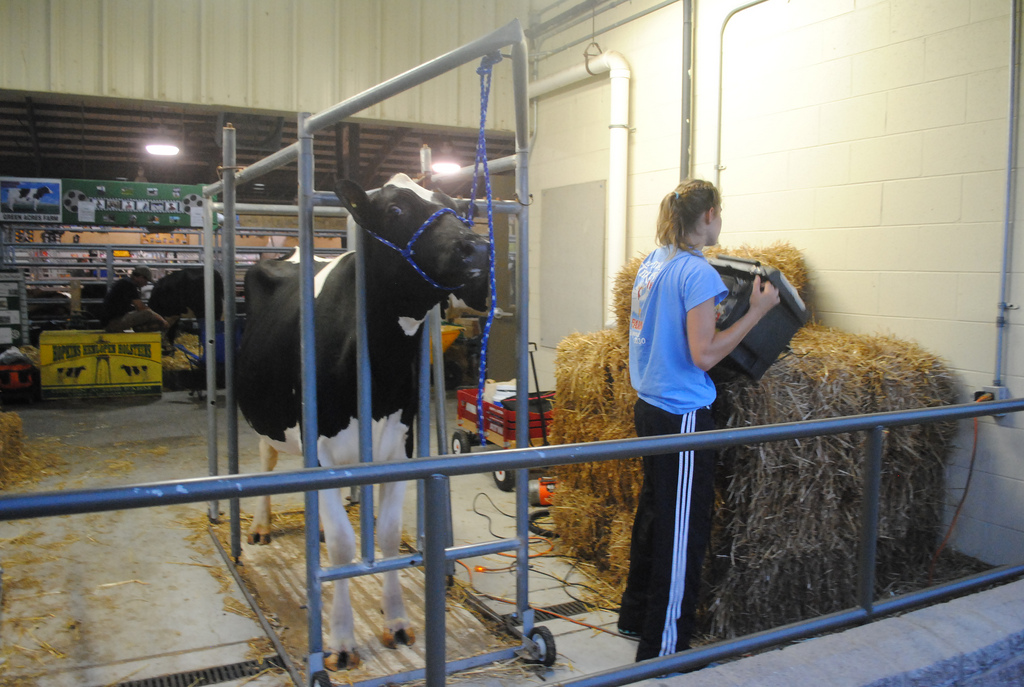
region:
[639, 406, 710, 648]
women is wearing pants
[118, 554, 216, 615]
the ground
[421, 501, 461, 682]
pole is grey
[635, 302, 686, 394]
the shirt is blue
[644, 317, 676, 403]
a blue shirt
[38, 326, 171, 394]
a yellow sign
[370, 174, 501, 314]
a cow that is black and white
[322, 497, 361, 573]
the cows leg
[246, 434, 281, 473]
the cows back leg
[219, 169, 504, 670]
Black and white cow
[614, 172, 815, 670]
Woman wearing black and white jogging pants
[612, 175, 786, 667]
Lady wearing blue shirt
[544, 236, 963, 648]
stack of brown hay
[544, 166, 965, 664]
Woman standing close to ray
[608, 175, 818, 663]
Woman in blue shirt carrying black bucket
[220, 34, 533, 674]
Blue rope on black and white cow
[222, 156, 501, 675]
Skinny black and white cow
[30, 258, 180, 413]
Guy sitting on yellow box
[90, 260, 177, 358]
Guy wearing brown hat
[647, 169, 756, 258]
the head of a woman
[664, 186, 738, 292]
the hair of a woman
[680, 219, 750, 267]
the chin of a woman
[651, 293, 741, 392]
the elbow of a woman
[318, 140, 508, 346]
the head of a cow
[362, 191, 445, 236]
the eye of a cow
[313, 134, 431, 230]
the ear of a cow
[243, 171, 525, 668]
A black and white cow in a shed.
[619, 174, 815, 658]
The woman hay handler.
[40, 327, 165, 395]
The yellow barrier in the background.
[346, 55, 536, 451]
The blue colored cow leash.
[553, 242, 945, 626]
A stack of hay.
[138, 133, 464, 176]
The ceiling lighting in the background.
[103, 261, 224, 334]
The man cattle handler.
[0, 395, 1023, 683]
The metallic cattle barrier.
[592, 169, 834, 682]
woman holding a basket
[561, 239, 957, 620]
large pile of hay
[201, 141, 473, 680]
black and white cow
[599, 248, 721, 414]
blue colored shirt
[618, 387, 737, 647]
black and white pants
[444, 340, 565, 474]
red wagon in the back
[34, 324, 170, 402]
yellow and black sign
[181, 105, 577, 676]
cow on a cart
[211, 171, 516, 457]
the cow is black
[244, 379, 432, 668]
white legs on cow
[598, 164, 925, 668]
woman standing next to hay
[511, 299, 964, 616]
a bail of hay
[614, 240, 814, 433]
girl holding a bin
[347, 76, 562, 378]
blue bridle on cow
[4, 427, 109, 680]
hay on the floor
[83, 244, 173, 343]
man in the background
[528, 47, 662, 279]
pipe on the wall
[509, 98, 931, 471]
girl in blue shirt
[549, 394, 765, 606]
black and white pants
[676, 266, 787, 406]
arm of the girl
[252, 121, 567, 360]
head of a cow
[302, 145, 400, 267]
ear of the cow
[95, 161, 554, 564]
black and white animal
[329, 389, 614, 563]
pole in front of cow